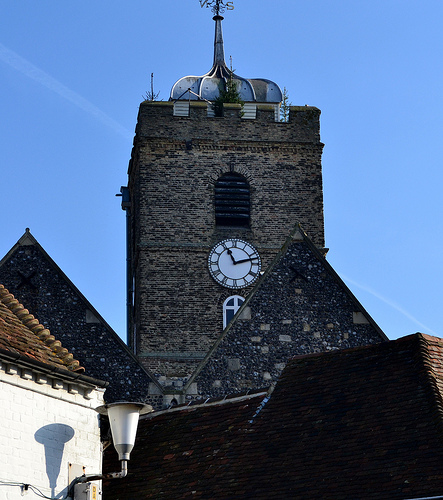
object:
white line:
[4, 46, 134, 145]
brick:
[306, 393, 339, 418]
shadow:
[34, 422, 78, 499]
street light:
[97, 394, 156, 478]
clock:
[179, 215, 336, 350]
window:
[208, 167, 255, 237]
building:
[0, 283, 112, 498]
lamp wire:
[7, 466, 49, 498]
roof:
[97, 330, 441, 498]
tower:
[95, 15, 343, 395]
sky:
[337, 51, 419, 183]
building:
[99, 8, 359, 407]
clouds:
[16, 58, 95, 116]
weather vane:
[196, 0, 236, 12]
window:
[226, 300, 239, 331]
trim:
[222, 293, 249, 332]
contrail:
[0, 35, 130, 145]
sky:
[16, 43, 115, 136]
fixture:
[96, 400, 152, 479]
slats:
[214, 178, 250, 216]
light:
[98, 397, 151, 474]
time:
[207, 240, 260, 281]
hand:
[221, 243, 237, 265]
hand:
[233, 254, 259, 264]